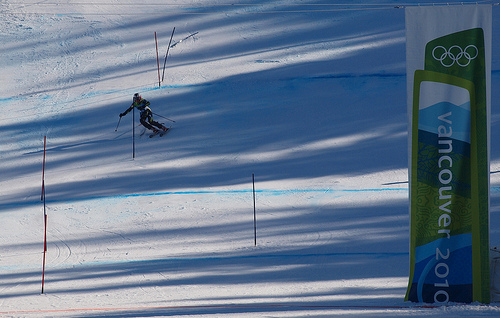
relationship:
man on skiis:
[120, 93, 169, 135] [147, 123, 167, 139]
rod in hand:
[114, 111, 124, 141] [120, 103, 131, 116]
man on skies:
[118, 90, 164, 136] [159, 125, 172, 136]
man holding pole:
[120, 93, 169, 135] [151, 109, 176, 130]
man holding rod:
[120, 93, 169, 135] [115, 117, 121, 131]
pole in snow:
[161, 20, 177, 83] [11, 4, 409, 312]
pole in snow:
[143, 28, 165, 94] [11, 4, 409, 312]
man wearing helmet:
[120, 93, 169, 135] [121, 80, 148, 100]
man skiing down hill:
[120, 93, 169, 135] [1, 2, 406, 311]